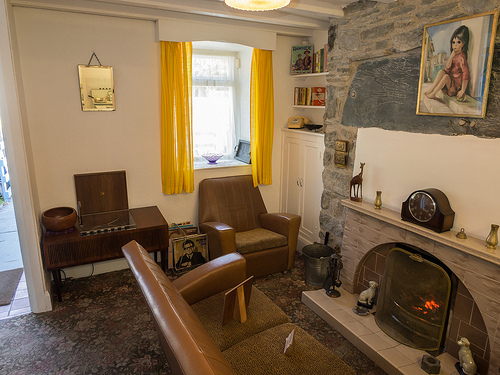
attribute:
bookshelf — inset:
[287, 32, 327, 132]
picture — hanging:
[415, 16, 495, 118]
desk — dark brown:
[53, 197, 207, 265]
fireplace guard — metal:
[372, 247, 453, 345]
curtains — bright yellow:
[243, 54, 296, 158]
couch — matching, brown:
[122, 239, 362, 373]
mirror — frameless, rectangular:
[75, 51, 120, 111]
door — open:
[0, 187, 40, 264]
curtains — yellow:
[159, 42, 276, 195]